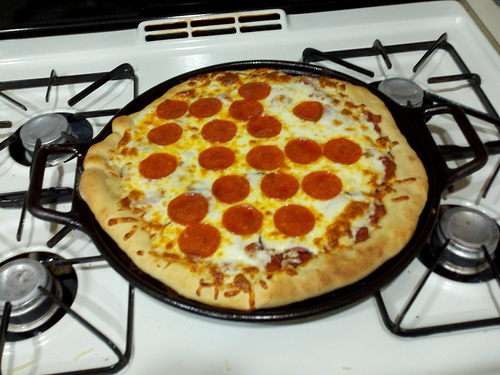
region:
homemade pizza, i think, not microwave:
[61, 62, 433, 317]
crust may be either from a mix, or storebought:
[70, 66, 434, 317]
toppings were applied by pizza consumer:
[113, 67, 398, 269]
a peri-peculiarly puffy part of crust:
[70, 102, 140, 212]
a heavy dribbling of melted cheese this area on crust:
[100, 192, 278, 314]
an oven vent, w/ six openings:
[137, 8, 292, 50]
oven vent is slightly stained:
[149, 8, 251, 44]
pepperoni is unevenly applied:
[142, 79, 362, 264]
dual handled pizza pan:
[24, 97, 486, 237]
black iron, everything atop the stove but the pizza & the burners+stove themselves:
[0, 38, 498, 374]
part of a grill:
[401, 313, 411, 326]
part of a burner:
[441, 204, 452, 229]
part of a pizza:
[273, 317, 288, 347]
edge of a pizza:
[182, 233, 201, 248]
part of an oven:
[177, 330, 194, 344]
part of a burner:
[44, 294, 63, 320]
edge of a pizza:
[111, 217, 131, 244]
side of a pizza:
[336, 156, 378, 184]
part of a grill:
[403, 288, 405, 330]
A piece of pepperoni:
[134, 151, 181, 178]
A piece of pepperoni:
[166, 191, 212, 223]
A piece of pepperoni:
[178, 225, 220, 260]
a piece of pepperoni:
[221, 205, 264, 238]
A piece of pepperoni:
[277, 204, 312, 238]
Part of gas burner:
[4, 197, 102, 371]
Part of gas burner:
[438, 184, 498, 322]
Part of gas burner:
[421, 42, 477, 123]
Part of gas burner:
[1, 82, 74, 169]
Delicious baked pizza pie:
[81, 55, 439, 315]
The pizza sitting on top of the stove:
[48, 30, 475, 352]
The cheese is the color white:
[136, 169, 213, 192]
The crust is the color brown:
[268, 236, 400, 292]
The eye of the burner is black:
[8, 191, 139, 372]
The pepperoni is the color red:
[204, 109, 246, 233]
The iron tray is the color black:
[362, 96, 484, 303]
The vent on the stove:
[136, 3, 298, 50]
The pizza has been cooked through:
[73, 25, 447, 312]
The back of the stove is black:
[8, 3, 138, 35]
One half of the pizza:
[263, 57, 435, 322]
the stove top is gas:
[12, 75, 92, 341]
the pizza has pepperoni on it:
[75, 60, 440, 325]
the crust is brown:
[305, 250, 361, 281]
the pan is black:
[73, 211, 101, 241]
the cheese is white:
[295, 118, 335, 134]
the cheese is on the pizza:
[299, 122, 349, 138]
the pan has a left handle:
[27, 133, 77, 243]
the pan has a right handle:
[415, 96, 493, 184]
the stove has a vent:
[130, 6, 291, 46]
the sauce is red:
[267, 247, 303, 269]